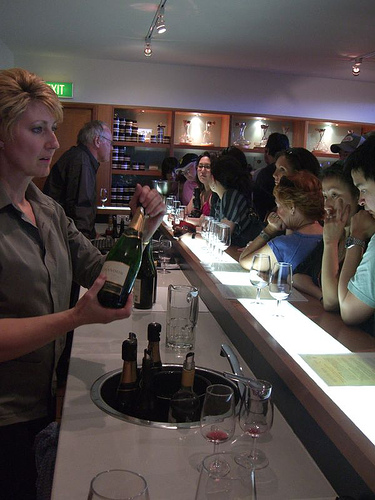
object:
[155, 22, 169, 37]
lighting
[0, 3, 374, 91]
ceiling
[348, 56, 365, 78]
lighting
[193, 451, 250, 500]
wine glass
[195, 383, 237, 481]
wine glass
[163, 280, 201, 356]
beer mug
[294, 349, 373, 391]
menu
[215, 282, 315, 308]
menu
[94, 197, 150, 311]
bottle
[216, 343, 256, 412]
faucet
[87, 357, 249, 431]
sink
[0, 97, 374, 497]
bar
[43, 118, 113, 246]
man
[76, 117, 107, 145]
hair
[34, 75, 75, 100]
sign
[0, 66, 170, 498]
woman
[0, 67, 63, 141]
hair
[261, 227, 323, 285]
shirt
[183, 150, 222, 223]
woman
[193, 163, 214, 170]
glasses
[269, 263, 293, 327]
wine glass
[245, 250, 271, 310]
wine glass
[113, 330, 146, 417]
bottle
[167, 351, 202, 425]
bottle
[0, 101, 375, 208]
shelves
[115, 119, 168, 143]
product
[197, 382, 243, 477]
wine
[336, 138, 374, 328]
people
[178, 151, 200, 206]
man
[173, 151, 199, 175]
cap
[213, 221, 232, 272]
glass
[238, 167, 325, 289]
woman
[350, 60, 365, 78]
spotlight